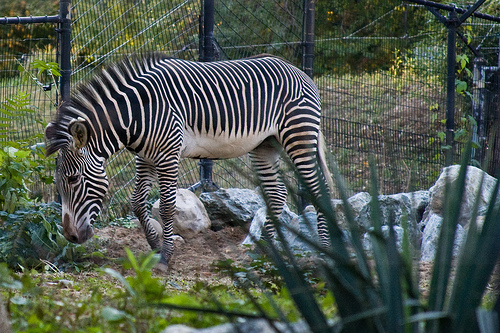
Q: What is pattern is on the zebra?
A: Black & white stripes.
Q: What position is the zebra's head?
A: Bent down towards the ground.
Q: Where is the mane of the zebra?
A: On neck.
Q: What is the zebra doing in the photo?
A: Grazing.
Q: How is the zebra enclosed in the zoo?
A: Fence.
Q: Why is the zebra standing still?
A: Enclosed in fence.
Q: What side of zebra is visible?
A: Left side.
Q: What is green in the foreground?
A: Plant leaves.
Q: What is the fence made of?
A: Metal.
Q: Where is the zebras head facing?
A: To the ground.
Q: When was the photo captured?
A: In the daytime.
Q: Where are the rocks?
A: By fence.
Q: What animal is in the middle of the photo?
A: Zebra.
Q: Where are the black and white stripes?
A: On the zebra.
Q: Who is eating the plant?
A: The zebra.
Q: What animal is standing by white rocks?
A: The zebra.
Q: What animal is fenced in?
A: A zebra.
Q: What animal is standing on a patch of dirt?
A: Zebra.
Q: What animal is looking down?
A: The zebra.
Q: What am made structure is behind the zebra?
A: Fence.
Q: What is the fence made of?
A: Metal.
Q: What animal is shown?
A: Zebra.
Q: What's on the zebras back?
A: Hair.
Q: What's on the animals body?
A: Stripes.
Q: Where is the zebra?
A: Zoo.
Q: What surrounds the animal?
A: Rocks.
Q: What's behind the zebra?
A: Fence.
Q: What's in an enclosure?
A: Zebra.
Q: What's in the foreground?
A: Plant.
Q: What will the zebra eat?
A: A mixture of grasses.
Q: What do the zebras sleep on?
A: A straw bed on the ground.